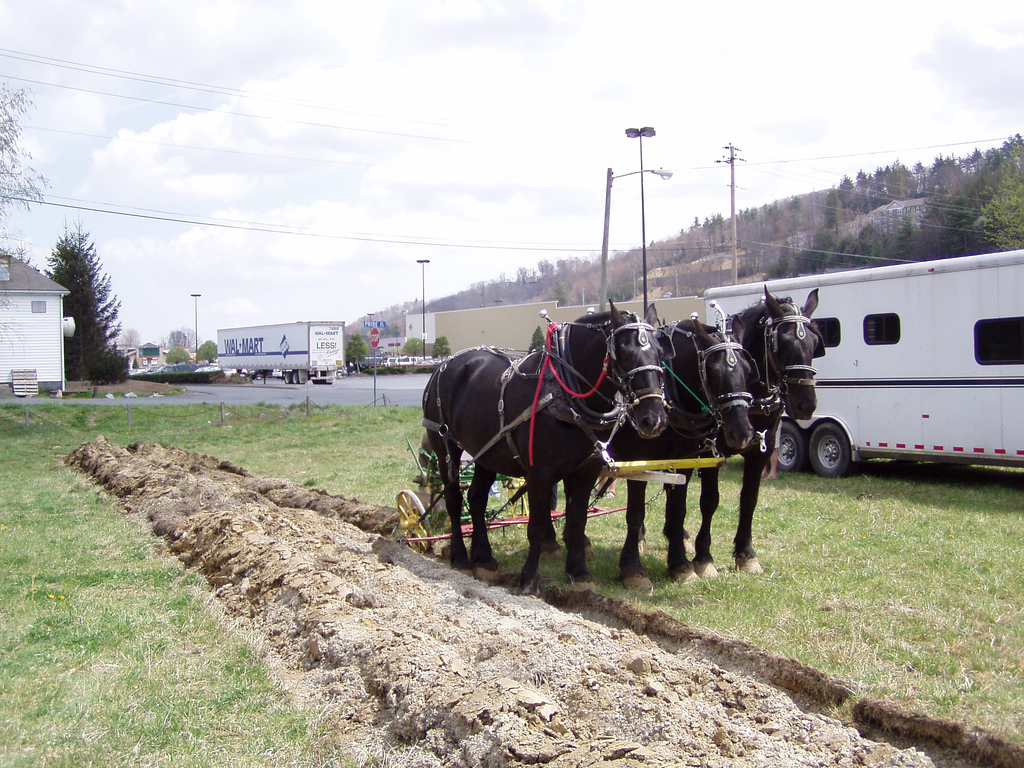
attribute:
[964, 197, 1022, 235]
leaves — green 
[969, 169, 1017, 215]
leaves — green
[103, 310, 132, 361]
leaves — green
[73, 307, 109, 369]
leaves — green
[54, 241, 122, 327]
leaves — green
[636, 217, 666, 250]
leaves — green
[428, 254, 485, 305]
leaves — green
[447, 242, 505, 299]
leaves — green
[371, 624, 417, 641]
scene —  outdoors 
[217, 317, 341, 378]
truck — large white walmart 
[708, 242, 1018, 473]
trailer — large white horse 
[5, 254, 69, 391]
house — white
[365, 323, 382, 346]
sign — red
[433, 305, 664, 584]
horse — black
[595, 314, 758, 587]
horse — black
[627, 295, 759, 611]
horse — black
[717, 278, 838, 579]
horse — black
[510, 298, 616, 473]
bridle — red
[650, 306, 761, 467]
bridle — green